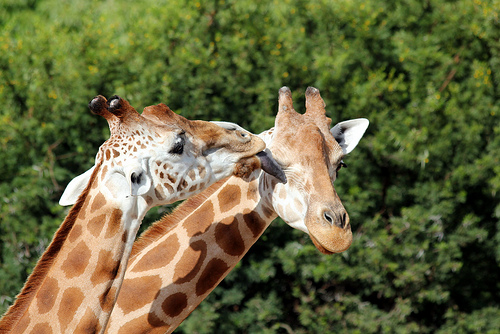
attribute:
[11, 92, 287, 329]
giraffe — licking, looking, both , brown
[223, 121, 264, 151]
nose — black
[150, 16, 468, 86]
trees — green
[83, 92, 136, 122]
horns — brown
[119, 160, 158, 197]
ear — white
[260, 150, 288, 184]
tongue — protuding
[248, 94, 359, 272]
giraffe — licked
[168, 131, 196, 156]
eyes — brown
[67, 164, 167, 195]
ears — brown